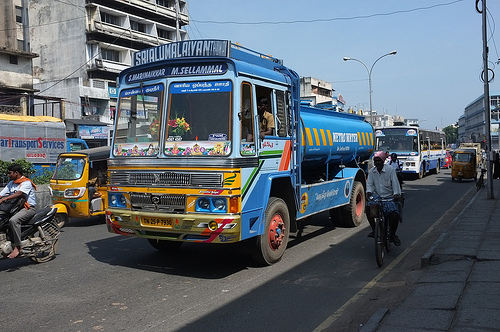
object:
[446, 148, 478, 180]
cab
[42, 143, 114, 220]
vehicle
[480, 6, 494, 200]
pole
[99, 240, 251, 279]
shadow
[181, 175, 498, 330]
shadow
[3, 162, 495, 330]
ground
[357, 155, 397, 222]
man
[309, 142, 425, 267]
shirt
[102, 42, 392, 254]
truck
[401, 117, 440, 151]
truck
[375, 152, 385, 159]
turban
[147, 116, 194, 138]
flowers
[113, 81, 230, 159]
windshield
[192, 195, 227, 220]
headlights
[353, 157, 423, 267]
bike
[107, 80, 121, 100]
window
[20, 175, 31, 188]
scarf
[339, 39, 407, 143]
lights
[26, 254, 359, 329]
street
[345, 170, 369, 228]
left wheel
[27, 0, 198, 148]
building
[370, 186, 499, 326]
sidewalk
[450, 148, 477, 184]
yellow car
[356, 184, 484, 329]
curb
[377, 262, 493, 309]
driveway